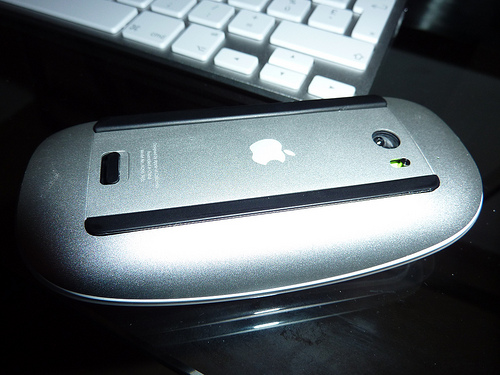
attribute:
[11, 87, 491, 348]
mouse — upside down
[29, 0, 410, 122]
keyboard — wireless, Apple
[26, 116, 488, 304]
mouse — silver 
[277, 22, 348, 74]
key — shift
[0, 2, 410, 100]
computer keyboard — bluetooth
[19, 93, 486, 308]
mouse — apple, upside down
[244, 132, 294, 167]
apple — white 